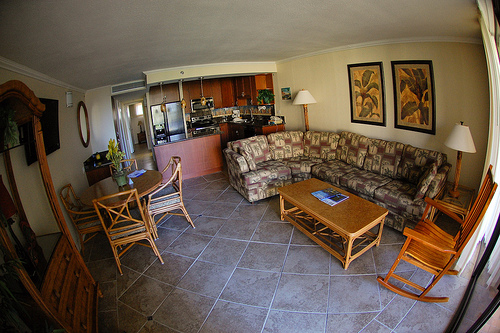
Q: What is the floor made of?
A: Tile.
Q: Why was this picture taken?
A: Advertisement.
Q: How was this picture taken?
A: From above.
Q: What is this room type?
A: A living room.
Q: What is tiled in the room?
A: The floors.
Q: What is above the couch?
A: Paintings.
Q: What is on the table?
A: Magazines.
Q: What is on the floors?
A: Tiles.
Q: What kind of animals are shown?
A: None.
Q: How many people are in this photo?
A: None.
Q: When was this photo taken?
A: Daytime.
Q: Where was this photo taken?
A: A home.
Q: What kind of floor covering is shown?
A: Tiles.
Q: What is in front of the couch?
A: A coffee table.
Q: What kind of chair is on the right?
A: Wooden.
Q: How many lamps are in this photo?
A: Two.